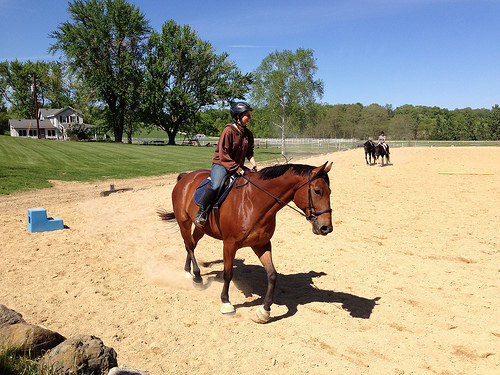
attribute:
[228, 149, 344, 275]
horse — brown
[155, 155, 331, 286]
horse — brown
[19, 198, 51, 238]
step — blue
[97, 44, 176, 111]
leaves — green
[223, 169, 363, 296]
horse — brown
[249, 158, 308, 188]
mane — black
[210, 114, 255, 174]
jacket — brown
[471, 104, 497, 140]
bush — green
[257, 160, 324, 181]
hair — black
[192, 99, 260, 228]
person —  young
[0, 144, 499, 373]
surface —  sandy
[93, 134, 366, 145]
fence —  white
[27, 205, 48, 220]
step —  blue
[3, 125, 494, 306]
land — flat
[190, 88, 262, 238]
person — riding, wearing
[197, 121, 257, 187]
sweatshirt — brown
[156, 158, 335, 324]
horse — brown,  brown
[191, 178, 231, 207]
blanket — blue